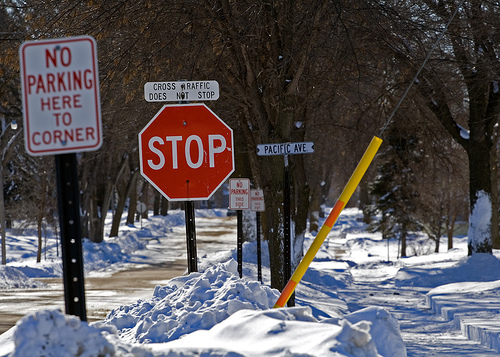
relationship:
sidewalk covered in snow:
[343, 224, 498, 354] [0, 189, 500, 357]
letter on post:
[139, 102, 235, 201] [182, 202, 199, 276]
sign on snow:
[227, 175, 250, 210] [0, 207, 498, 355]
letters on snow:
[18, 36, 101, 156] [0, 207, 498, 355]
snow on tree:
[463, 186, 495, 252] [357, 2, 499, 260]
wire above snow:
[265, 1, 467, 311] [0, 189, 500, 357]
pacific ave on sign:
[265, 139, 308, 157] [254, 132, 333, 160]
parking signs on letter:
[145, 80, 217, 101] [139, 102, 235, 201]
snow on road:
[0, 189, 500, 357] [0, 213, 241, 337]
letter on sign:
[146, 133, 225, 173] [139, 100, 236, 206]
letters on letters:
[54, 75, 89, 112] [18, 36, 101, 156]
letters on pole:
[18, 36, 101, 156] [52, 150, 89, 326]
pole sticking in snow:
[179, 199, 199, 273] [166, 275, 244, 341]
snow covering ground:
[140, 277, 224, 347] [0, 204, 500, 354]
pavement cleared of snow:
[6, 201, 243, 355] [183, 309, 292, 354]